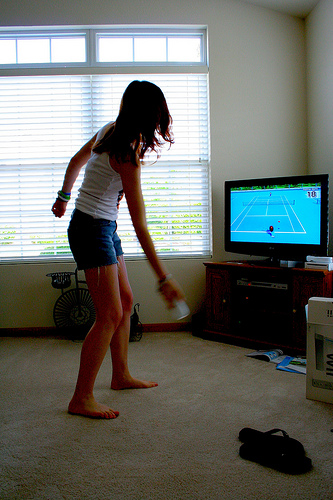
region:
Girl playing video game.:
[46, 77, 194, 422]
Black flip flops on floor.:
[234, 423, 314, 482]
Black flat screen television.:
[222, 171, 329, 267]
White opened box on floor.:
[304, 294, 331, 405]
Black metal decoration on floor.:
[44, 255, 150, 346]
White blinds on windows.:
[0, 76, 213, 260]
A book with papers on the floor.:
[246, 348, 309, 372]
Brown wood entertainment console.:
[197, 260, 332, 364]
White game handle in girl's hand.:
[169, 294, 191, 320]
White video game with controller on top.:
[303, 249, 332, 272]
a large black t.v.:
[211, 171, 331, 261]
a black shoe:
[235, 437, 315, 475]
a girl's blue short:
[64, 211, 124, 271]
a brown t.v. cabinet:
[198, 262, 331, 350]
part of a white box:
[298, 295, 332, 401]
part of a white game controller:
[173, 300, 189, 321]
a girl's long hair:
[89, 78, 179, 166]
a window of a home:
[95, 38, 201, 62]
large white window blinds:
[2, 76, 208, 260]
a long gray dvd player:
[235, 278, 288, 291]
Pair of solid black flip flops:
[239, 427, 312, 474]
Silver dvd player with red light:
[236, 279, 285, 290]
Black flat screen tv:
[223, 180, 330, 253]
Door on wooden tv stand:
[204, 265, 231, 332]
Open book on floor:
[246, 347, 286, 364]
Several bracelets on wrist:
[56, 189, 70, 201]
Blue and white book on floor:
[285, 355, 304, 371]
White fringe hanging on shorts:
[94, 264, 99, 285]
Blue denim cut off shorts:
[72, 211, 116, 262]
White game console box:
[305, 301, 331, 399]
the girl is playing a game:
[59, 74, 190, 425]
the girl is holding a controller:
[158, 270, 188, 328]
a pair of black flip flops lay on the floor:
[233, 411, 312, 481]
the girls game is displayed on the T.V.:
[224, 176, 323, 255]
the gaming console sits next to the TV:
[303, 249, 331, 273]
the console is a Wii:
[298, 261, 332, 269]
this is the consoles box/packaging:
[303, 292, 331, 410]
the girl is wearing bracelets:
[55, 184, 73, 207]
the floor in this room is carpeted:
[23, 320, 317, 496]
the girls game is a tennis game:
[136, 168, 326, 326]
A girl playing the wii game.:
[67, 66, 201, 354]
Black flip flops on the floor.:
[223, 405, 325, 494]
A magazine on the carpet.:
[257, 348, 311, 378]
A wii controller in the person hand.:
[163, 291, 195, 317]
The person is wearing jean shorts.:
[69, 208, 129, 253]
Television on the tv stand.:
[222, 171, 331, 268]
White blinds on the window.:
[17, 90, 195, 241]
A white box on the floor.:
[287, 301, 332, 390]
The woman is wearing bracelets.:
[52, 180, 74, 206]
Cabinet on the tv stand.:
[207, 269, 226, 332]